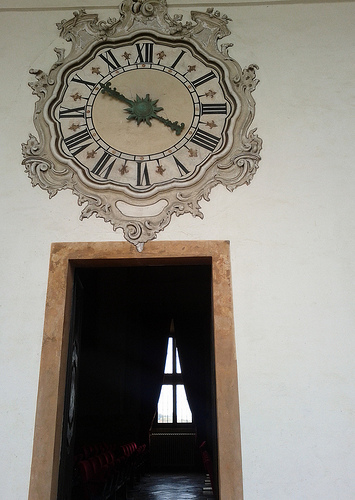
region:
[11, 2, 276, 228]
The numbers of the clock are in roman numerals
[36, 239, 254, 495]
The doorway is made out of beige marble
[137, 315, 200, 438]
There are drapes on the window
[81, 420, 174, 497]
Red, fold up seats line the inside of the room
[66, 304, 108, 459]
A movie screen has a woman on it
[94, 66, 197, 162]
The clock has green hands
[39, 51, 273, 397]
The clock hangs over the doorway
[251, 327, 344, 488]
The walls are white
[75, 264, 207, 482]
The inside of the room is dark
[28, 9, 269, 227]
The clock is beige, green, black and white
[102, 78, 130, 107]
a hand on a clock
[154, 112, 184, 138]
a hand on a clock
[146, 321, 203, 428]
a window with curtains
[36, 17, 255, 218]
a clock on a wall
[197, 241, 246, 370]
a brown door frame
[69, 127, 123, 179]
roman numerals on a clock face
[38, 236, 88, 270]
a corner of a doorway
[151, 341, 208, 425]
light coming through the window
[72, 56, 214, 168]
a clock with roman numeral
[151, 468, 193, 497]
reflection of light on the floor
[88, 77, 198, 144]
green old aged hour and minute hand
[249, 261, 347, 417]
white painted living room wall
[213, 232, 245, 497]
light brown wood trim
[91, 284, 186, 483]
dark portion of the room inside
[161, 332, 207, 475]
window pane of bedroom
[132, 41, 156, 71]
roman numeral letters on clock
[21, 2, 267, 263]
white ancient designed clock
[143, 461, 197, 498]
shiny dark hardwood floor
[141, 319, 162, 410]
black curtains inside room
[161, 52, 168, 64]
gold accent on clock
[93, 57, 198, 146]
Hands on the clock.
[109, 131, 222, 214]
Roman numerals on the clock.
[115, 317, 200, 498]
Window in the room.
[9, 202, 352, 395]
Door into a room.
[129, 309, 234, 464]
Curtains partially covering the window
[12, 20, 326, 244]
clock on the wall.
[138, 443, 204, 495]
Tile floor by the window.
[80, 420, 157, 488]
Red couch in the room.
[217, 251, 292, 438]
Wood edging on the door.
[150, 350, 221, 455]
Panes on the window.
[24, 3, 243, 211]
Large clock hanging on wall.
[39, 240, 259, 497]
Large doorway in building.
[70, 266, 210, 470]
Dark space inside building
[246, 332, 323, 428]
Gray colored wall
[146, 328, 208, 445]
Open window inside building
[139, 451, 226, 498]
Sun shadow cast on floor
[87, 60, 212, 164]
Center dial on clock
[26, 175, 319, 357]
Brown colored door frame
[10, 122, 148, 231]
Scroll decoration on clock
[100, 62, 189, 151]
Antique style dial